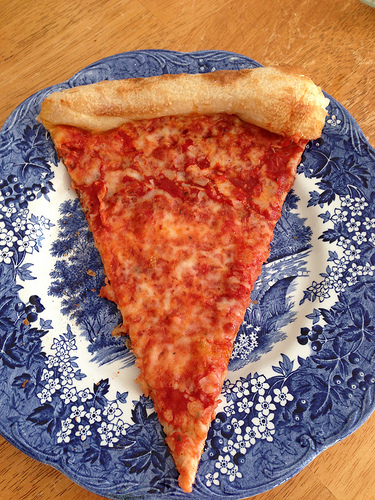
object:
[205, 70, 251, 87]
spot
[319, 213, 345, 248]
leaves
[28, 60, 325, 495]
triangle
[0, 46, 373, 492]
design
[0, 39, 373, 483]
plate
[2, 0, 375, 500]
table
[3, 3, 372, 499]
wood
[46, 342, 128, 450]
flower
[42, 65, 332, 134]
crust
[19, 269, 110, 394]
crumbs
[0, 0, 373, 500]
wooden table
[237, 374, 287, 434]
flowers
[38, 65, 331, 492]
slice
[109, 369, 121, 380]
stain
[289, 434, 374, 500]
clean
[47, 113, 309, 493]
sauce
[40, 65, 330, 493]
cheese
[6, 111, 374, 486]
flower design